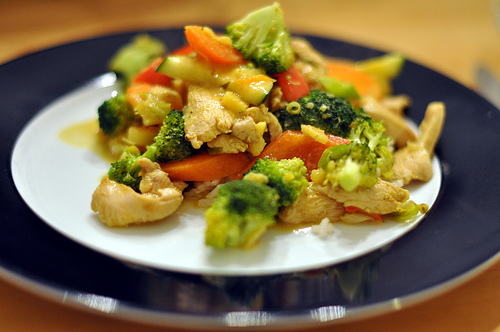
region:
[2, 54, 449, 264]
the plate is white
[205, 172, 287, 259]
broccoli on the plate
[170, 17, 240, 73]
tomatoes on the plate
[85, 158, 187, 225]
chicken on the plate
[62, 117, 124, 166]
yellow sauce on the plate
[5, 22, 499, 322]
the plate is blue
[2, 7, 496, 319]
the plate is shiny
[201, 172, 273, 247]
the broccoli is green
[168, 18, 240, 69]
the tomatoes are red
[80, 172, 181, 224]
the chicken is tan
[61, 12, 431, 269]
plate of food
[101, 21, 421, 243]
many items on plate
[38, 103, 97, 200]
white plate under food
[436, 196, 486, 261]
blue plate next to food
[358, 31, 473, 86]
blurry table in background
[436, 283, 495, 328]
brown table beneath plate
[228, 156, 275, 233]
broccoli on plate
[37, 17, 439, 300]
food on two different plates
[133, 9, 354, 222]
food stacked on top of itself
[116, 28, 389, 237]
green, yellow, orange and white food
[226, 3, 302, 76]
a piece of green broccoli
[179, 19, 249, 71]
an orange pepper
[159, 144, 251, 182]
a piece of carrot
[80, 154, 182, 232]
a brown piece of chicken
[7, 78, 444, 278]
a round white plate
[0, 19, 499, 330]
a blue and white plate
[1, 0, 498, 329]
a brown table under the plate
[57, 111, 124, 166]
sauce on the plate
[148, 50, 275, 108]
a piece of zucchini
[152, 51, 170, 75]
the peel of the zucchini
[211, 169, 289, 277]
Green broccoli on plate.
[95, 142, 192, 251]
Chicken cut up in pieces on plate.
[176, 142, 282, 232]
Sliced carrots on plate.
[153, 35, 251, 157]
Cut up zucchini on plate.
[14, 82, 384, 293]
Plate is white and blue.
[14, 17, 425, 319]
Plate has blue outer edge.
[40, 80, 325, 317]
Center of plate is white.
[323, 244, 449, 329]
Plate is sitting on a brown surface.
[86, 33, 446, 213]
Food is piled in the center of the plate.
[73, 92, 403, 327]
Yellow sauce on top of food.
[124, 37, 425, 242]
food on a plate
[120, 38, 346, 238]
vegetables on a plate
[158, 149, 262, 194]
A carrot on a plate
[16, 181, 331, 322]
A white plate with a blue rim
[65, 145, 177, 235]
chicken on a plate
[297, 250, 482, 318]
the edge of a plate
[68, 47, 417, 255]
healthy food on a plate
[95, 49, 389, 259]
Not a vegetarian dish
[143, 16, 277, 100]
cooked zucchini and carrots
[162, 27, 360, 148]
cooked zucchini and carrots with broccoli